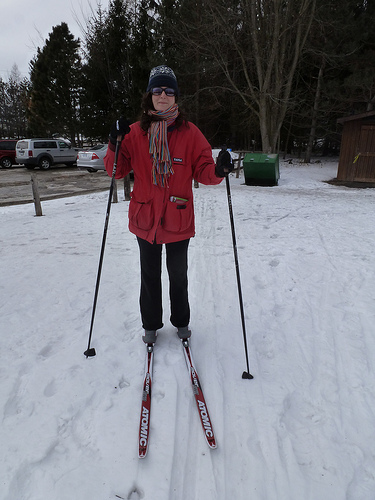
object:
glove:
[211, 147, 234, 178]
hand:
[109, 117, 131, 148]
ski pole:
[81, 132, 124, 361]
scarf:
[147, 103, 181, 187]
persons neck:
[142, 105, 178, 126]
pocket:
[128, 196, 158, 235]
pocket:
[162, 199, 194, 232]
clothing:
[104, 99, 234, 329]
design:
[144, 61, 182, 81]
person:
[98, 56, 228, 345]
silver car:
[76, 140, 109, 172]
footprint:
[43, 362, 73, 394]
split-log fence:
[2, 172, 133, 217]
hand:
[213, 142, 234, 176]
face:
[147, 84, 177, 117]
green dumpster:
[240, 151, 281, 186]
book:
[168, 195, 188, 201]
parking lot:
[0, 153, 134, 207]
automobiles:
[14, 136, 79, 171]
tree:
[21, 25, 85, 146]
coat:
[92, 113, 228, 244]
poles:
[219, 166, 254, 381]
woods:
[1, 0, 375, 159]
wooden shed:
[327, 109, 373, 189]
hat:
[143, 62, 179, 96]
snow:
[0, 152, 375, 497]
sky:
[3, 0, 148, 94]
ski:
[179, 331, 219, 450]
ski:
[134, 332, 154, 459]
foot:
[175, 317, 191, 342]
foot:
[140, 317, 161, 347]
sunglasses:
[150, 85, 178, 102]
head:
[147, 65, 178, 116]